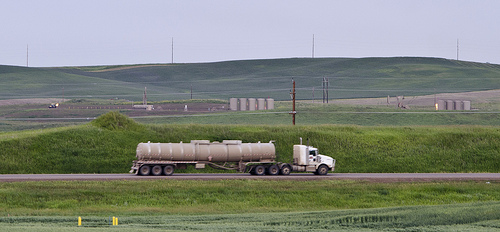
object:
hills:
[0, 56, 500, 109]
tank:
[135, 139, 276, 161]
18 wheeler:
[129, 137, 337, 176]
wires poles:
[323, 76, 328, 104]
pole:
[312, 34, 314, 58]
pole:
[457, 39, 458, 60]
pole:
[172, 37, 174, 64]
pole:
[27, 44, 28, 67]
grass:
[84, 180, 115, 207]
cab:
[293, 145, 319, 164]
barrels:
[228, 98, 273, 111]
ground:
[237, 111, 288, 123]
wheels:
[139, 165, 174, 175]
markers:
[76, 216, 118, 226]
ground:
[0, 175, 497, 230]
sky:
[0, 0, 500, 67]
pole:
[289, 78, 296, 126]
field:
[1, 178, 500, 232]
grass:
[0, 178, 27, 208]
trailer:
[129, 137, 336, 176]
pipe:
[299, 137, 302, 145]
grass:
[324, 181, 497, 190]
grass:
[35, 180, 75, 213]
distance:
[21, 60, 494, 137]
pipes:
[229, 98, 238, 111]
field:
[156, 78, 500, 113]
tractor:
[292, 137, 336, 175]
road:
[0, 173, 500, 183]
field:
[0, 113, 500, 173]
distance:
[3, 35, 494, 75]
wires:
[302, 76, 472, 92]